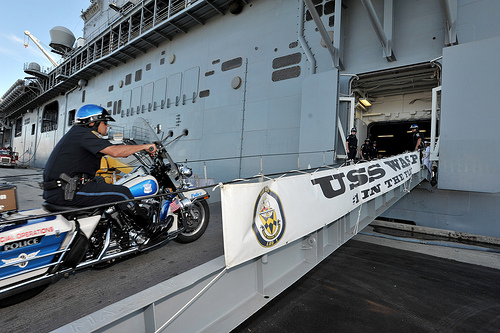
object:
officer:
[40, 98, 175, 241]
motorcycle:
[0, 112, 217, 306]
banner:
[217, 151, 426, 268]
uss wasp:
[310, 150, 421, 199]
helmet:
[73, 101, 117, 124]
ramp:
[191, 147, 421, 333]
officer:
[343, 126, 360, 165]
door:
[343, 59, 448, 169]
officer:
[359, 137, 374, 163]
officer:
[407, 122, 426, 156]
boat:
[0, 0, 500, 269]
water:
[356, 229, 493, 257]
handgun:
[57, 168, 80, 203]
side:
[61, 137, 106, 208]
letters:
[15, 231, 23, 242]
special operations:
[0, 222, 57, 244]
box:
[0, 180, 21, 215]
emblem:
[247, 185, 290, 250]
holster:
[55, 170, 88, 202]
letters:
[308, 171, 348, 199]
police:
[2, 237, 40, 251]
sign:
[0, 247, 42, 271]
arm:
[94, 140, 156, 159]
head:
[74, 102, 114, 138]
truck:
[0, 144, 20, 170]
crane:
[19, 28, 57, 70]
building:
[20, 57, 90, 98]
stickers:
[0, 192, 7, 202]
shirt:
[41, 123, 113, 195]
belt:
[36, 172, 99, 189]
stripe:
[76, 188, 125, 197]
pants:
[41, 175, 151, 228]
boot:
[141, 212, 179, 243]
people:
[369, 137, 381, 158]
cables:
[14, 135, 42, 165]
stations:
[44, 24, 78, 51]